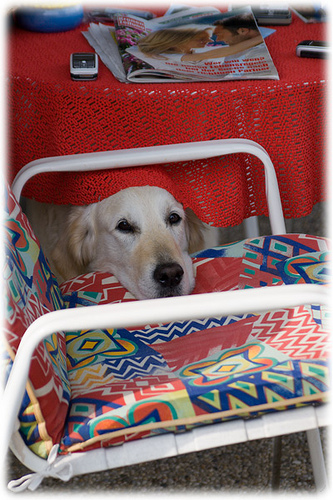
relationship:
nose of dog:
[150, 259, 185, 289] [94, 204, 217, 301]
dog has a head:
[60, 169, 216, 310] [64, 183, 197, 307]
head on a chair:
[64, 183, 197, 307] [4, 137, 332, 490]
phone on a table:
[69, 52, 99, 80] [10, 7, 324, 234]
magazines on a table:
[80, 15, 279, 86] [10, 7, 324, 234]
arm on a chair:
[12, 139, 281, 201] [4, 136, 332, 494]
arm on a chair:
[4, 274, 330, 478] [4, 136, 332, 494]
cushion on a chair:
[1, 154, 68, 466] [6, 132, 299, 367]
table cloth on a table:
[10, 2, 332, 227] [10, 7, 324, 234]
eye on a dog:
[110, 215, 139, 238] [20, 183, 210, 300]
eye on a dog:
[161, 208, 181, 228] [20, 183, 210, 300]